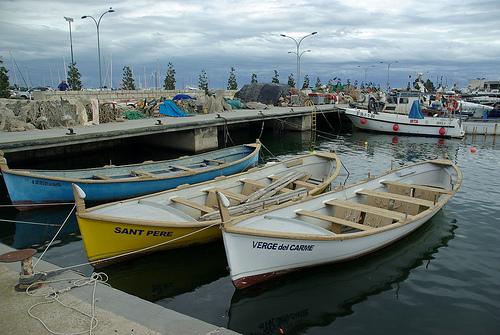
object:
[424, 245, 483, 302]
water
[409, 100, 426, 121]
shirt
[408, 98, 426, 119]
man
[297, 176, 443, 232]
bench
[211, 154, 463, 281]
boat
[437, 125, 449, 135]
saver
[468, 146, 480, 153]
buoy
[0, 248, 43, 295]
post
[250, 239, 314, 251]
name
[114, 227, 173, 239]
name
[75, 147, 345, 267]
boat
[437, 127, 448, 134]
balloons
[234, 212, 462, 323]
reflection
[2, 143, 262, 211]
boat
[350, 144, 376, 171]
water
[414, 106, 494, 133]
boat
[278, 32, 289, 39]
light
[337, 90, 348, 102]
pole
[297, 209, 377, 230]
seat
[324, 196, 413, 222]
seat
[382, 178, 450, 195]
seat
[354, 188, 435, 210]
seat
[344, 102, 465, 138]
boat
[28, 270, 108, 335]
rope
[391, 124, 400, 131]
buoy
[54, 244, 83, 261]
water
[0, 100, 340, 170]
dock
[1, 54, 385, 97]
trees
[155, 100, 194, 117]
tarp